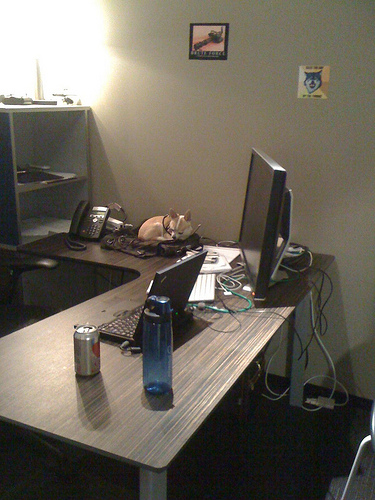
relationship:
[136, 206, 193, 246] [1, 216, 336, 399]
dog on desk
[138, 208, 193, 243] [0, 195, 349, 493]
dog on desk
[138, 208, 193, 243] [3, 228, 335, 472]
dog on desk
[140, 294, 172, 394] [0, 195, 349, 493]
bottle on desk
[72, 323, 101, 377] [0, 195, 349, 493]
can on desk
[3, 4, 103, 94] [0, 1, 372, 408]
sunlight on wall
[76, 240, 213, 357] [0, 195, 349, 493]
laptop on desk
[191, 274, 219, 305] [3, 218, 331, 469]
keyboard on wood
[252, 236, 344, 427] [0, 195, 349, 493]
cord on desk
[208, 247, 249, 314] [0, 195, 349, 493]
cord on desk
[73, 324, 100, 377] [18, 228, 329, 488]
can on desk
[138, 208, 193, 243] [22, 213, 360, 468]
dog on desk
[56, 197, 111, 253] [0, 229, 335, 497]
phone sitting on computer desk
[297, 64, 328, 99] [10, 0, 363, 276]
picture on wall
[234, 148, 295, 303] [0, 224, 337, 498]
computer on desk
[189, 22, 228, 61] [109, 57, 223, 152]
picture hanging on wall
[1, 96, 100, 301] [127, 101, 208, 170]
cabinet against wall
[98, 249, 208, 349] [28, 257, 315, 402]
laptop in foreground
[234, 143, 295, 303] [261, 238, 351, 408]
computer and electronic plugs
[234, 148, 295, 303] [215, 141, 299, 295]
computer computer screen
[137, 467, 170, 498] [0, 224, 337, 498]
leg of desk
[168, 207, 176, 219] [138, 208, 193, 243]
ear of dog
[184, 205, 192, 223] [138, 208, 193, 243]
ear of dog